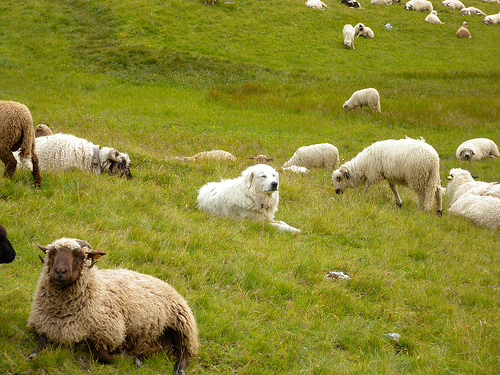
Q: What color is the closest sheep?
A: Brown.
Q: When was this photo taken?
A: During the day.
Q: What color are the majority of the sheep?
A: White.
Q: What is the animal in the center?
A: A dog.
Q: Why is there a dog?
A: To guard the sheep.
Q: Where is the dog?
A: Among the sheep.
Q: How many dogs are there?
A: 1.